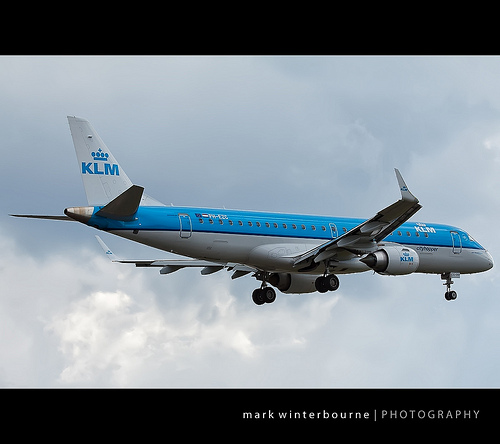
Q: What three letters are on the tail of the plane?
A: KLM.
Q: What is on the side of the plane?
A: Windows.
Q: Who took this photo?
A: Mark Winterbourne.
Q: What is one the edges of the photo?
A: Black borders.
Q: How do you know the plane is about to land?
A: Landing gear is down.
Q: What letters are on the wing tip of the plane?
A: KLM.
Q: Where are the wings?
A: Side of plane.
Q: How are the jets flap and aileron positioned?
A: Down.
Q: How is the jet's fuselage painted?
A: Blue and gray.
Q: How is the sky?
A: Cloudy.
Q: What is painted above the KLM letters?
A: Crown.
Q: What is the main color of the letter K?
A: Blue.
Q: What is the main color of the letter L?
A: Blue.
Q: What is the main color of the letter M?
A: Blue.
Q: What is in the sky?
A: A plane.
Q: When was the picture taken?
A: Daytime.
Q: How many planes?
A: 1.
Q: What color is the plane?
A: Blue.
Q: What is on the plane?
A: KLM.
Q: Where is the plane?
A: The sky.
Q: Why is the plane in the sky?
A: To fly.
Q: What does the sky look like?
A: Cloudy.